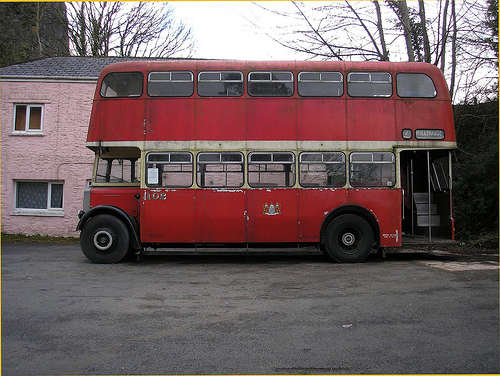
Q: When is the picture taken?
A: Daytime.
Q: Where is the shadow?
A: In the road.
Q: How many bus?
A: 1.